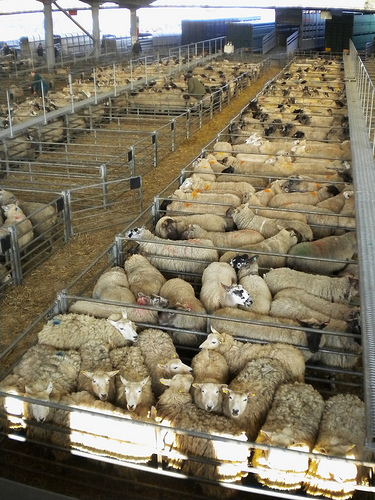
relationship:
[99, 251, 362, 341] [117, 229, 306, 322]
pen filled with sheep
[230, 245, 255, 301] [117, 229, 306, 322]
faces of sheep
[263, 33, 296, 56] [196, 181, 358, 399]
ramp ofr loading animals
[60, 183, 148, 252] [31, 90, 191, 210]
gate to pens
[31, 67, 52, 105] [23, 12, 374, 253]
person in building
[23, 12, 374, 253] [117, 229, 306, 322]
building holds sheep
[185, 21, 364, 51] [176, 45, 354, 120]
loading dock near animal pens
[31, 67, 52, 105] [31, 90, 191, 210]
person near pens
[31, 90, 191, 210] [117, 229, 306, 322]
pens filled with sheep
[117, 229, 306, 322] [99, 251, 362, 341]
sheep in pen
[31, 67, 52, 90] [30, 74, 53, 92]
person wearing jacket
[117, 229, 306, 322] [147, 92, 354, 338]
sheep in cages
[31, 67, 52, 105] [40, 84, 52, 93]
person has jacket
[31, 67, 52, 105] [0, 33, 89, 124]
person in pen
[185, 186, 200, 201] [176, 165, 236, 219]
marking on back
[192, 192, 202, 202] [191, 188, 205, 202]
tags on ears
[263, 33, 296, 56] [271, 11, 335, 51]
ramp to truck